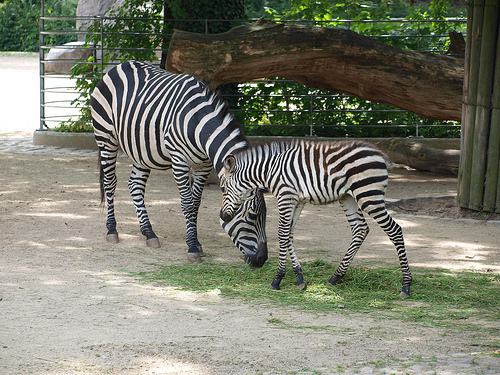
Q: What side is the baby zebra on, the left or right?
A: Right.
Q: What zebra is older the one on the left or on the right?
A: Left.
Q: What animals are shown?
A: Zebras.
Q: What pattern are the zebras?
A: Striped.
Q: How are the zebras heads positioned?
A: They are bent.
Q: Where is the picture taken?
A: A zoo.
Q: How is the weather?
A: Clear and sunny.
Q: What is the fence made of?
A: Metal.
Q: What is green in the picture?
A: Grass.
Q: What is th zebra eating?
A: Grass.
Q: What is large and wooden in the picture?
A: A tree trunk.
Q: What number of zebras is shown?
A: Two.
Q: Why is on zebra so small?
A: It a baby.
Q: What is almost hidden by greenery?
A: A fence.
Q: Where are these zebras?
A: In an enclosure.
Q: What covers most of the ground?
A: Dirt.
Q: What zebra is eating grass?
A: The big one.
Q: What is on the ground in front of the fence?
A: A log.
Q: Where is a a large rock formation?
A: Behind the fence.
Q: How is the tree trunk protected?
A: With bamboo.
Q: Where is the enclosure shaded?
A: In front of the fence.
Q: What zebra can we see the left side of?
A: The baby.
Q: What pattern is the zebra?
A: Striped.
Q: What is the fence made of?
A: Metal.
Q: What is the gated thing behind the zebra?
A: Fence.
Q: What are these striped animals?
A: Zebras.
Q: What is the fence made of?
A: Metal poles.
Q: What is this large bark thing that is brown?
A: Tree trunk.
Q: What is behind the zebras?
A: A log.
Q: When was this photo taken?
A: Day time.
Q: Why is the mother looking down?
A: To eat.